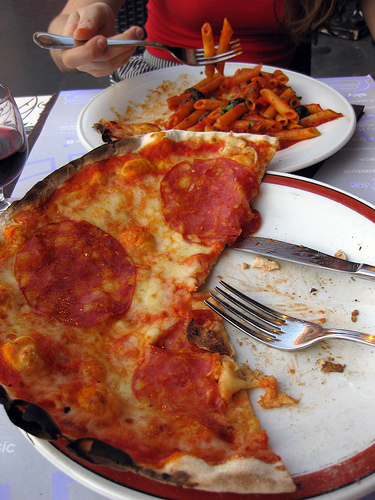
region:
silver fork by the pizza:
[199, 275, 374, 348]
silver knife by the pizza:
[229, 231, 373, 280]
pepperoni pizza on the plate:
[0, 127, 298, 495]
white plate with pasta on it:
[74, 59, 361, 172]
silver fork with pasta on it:
[30, 29, 244, 68]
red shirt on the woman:
[143, 0, 321, 79]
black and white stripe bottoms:
[102, 47, 182, 85]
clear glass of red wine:
[0, 77, 30, 214]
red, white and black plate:
[17, 170, 373, 499]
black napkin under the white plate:
[289, 101, 366, 180]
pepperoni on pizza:
[12, 218, 134, 327]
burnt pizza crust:
[0, 380, 192, 491]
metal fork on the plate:
[205, 278, 373, 351]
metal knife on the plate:
[228, 234, 373, 281]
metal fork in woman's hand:
[33, 31, 240, 63]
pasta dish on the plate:
[166, 18, 335, 142]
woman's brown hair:
[271, 0, 346, 44]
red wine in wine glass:
[0, 83, 25, 213]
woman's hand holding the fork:
[61, 0, 142, 76]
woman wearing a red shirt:
[148, 0, 308, 76]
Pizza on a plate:
[41, 188, 363, 484]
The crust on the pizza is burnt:
[7, 411, 90, 454]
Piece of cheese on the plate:
[246, 358, 307, 429]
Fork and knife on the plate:
[196, 220, 368, 344]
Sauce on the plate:
[256, 286, 296, 310]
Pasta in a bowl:
[153, 76, 333, 179]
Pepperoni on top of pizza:
[146, 159, 267, 250]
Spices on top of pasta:
[205, 90, 243, 115]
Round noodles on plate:
[205, 77, 267, 132]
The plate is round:
[309, 439, 363, 491]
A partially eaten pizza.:
[35, 129, 292, 297]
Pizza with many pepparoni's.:
[8, 214, 160, 344]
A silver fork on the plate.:
[187, 277, 353, 376]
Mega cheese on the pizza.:
[102, 215, 217, 322]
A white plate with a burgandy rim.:
[290, 434, 371, 498]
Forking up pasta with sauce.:
[101, 18, 254, 86]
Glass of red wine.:
[3, 81, 32, 197]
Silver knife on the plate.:
[203, 229, 368, 276]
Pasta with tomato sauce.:
[142, 61, 320, 139]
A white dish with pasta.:
[88, 70, 257, 138]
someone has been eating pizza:
[1, 137, 373, 496]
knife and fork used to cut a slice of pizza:
[199, 233, 374, 350]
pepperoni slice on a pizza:
[10, 221, 141, 327]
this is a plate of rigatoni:
[75, 18, 361, 176]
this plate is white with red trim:
[0, 166, 369, 496]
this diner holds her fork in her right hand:
[31, 0, 247, 79]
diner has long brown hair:
[267, 0, 353, 54]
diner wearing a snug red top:
[139, 1, 312, 65]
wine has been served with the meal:
[0, 81, 32, 218]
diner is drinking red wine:
[0, 80, 31, 215]